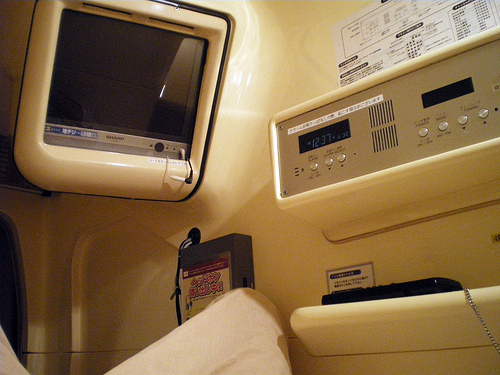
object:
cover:
[325, 262, 375, 294]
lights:
[309, 127, 336, 147]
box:
[178, 233, 254, 328]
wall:
[26, 203, 179, 328]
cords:
[164, 145, 197, 186]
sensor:
[151, 142, 166, 153]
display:
[43, 6, 211, 161]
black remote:
[320, 277, 463, 305]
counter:
[291, 285, 500, 355]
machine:
[6, 0, 240, 205]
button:
[337, 153, 343, 159]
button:
[308, 160, 318, 170]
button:
[323, 158, 332, 167]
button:
[335, 153, 347, 161]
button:
[435, 122, 449, 130]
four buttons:
[416, 105, 492, 138]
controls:
[264, 23, 499, 238]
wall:
[242, 0, 301, 62]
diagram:
[336, 0, 498, 89]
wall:
[393, 225, 476, 275]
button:
[175, 145, 186, 163]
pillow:
[106, 282, 294, 374]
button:
[418, 125, 429, 137]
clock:
[297, 119, 351, 155]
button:
[478, 106, 490, 121]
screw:
[272, 122, 278, 130]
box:
[262, 27, 497, 246]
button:
[457, 116, 469, 129]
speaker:
[367, 101, 407, 155]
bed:
[0, 287, 500, 375]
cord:
[456, 288, 500, 353]